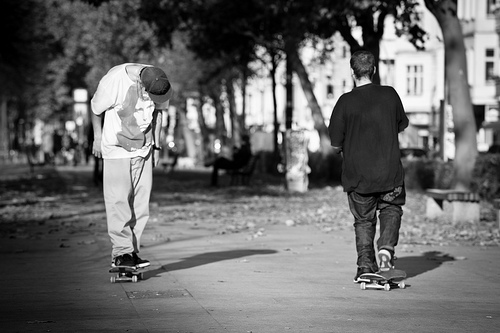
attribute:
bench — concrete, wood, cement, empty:
[424, 187, 482, 226]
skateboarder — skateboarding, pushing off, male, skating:
[327, 49, 412, 293]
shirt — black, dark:
[327, 82, 412, 198]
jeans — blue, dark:
[345, 181, 407, 271]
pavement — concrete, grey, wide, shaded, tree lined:
[4, 169, 500, 332]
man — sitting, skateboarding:
[201, 132, 253, 189]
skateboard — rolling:
[109, 258, 151, 285]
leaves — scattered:
[0, 179, 499, 259]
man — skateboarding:
[91, 61, 175, 267]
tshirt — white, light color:
[91, 62, 172, 161]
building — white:
[443, 2, 499, 158]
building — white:
[359, 0, 444, 162]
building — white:
[290, 8, 356, 152]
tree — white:
[248, 43, 291, 157]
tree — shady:
[287, 7, 333, 174]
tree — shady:
[209, 14, 241, 170]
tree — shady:
[181, 21, 214, 173]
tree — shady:
[253, 8, 288, 169]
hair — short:
[349, 46, 376, 82]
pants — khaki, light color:
[102, 148, 155, 260]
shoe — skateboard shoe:
[113, 251, 139, 272]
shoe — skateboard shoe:
[132, 252, 151, 269]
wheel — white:
[132, 275, 138, 284]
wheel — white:
[108, 274, 117, 284]